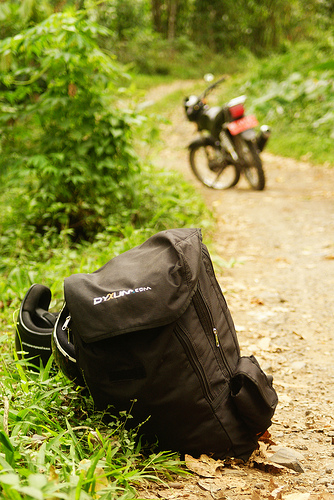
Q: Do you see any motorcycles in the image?
A: Yes, there is a motorcycle.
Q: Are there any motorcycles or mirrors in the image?
A: Yes, there is a motorcycle.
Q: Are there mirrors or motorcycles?
A: Yes, there is a motorcycle.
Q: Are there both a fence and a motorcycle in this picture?
A: No, there is a motorcycle but no fences.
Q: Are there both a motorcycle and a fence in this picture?
A: No, there is a motorcycle but no fences.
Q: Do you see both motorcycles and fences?
A: No, there is a motorcycle but no fences.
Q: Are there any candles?
A: No, there are no candles.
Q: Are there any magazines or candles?
A: No, there are no candles or magazines.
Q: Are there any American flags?
A: No, there are no American flags.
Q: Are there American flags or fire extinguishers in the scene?
A: No, there are no American flags or fire extinguishers.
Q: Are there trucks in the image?
A: No, there are no trucks.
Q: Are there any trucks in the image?
A: No, there are no trucks.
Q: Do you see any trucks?
A: No, there are no trucks.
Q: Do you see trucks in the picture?
A: No, there are no trucks.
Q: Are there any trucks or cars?
A: No, there are no trucks or cars.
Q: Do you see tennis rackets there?
A: No, there are no tennis rackets.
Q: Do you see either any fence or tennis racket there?
A: No, there are no rackets or fences.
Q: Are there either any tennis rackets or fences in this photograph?
A: No, there are no tennis rackets or fences.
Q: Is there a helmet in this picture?
A: Yes, there is a helmet.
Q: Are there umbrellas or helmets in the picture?
A: Yes, there is a helmet.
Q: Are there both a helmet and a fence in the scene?
A: No, there is a helmet but no fences.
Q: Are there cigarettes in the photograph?
A: No, there are no cigarettes.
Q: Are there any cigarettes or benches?
A: No, there are no cigarettes or benches.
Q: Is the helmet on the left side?
A: Yes, the helmet is on the left of the image.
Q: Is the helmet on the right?
A: No, the helmet is on the left of the image.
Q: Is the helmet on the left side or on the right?
A: The helmet is on the left of the image.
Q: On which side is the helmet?
A: The helmet is on the left of the image.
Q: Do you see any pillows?
A: No, there are no pillows.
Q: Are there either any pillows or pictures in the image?
A: No, there are no pillows or pictures.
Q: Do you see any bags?
A: Yes, there is a bag.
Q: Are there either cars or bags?
A: Yes, there is a bag.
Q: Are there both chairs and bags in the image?
A: No, there is a bag but no chairs.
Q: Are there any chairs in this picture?
A: No, there are no chairs.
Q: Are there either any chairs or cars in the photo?
A: No, there are no chairs or cars.